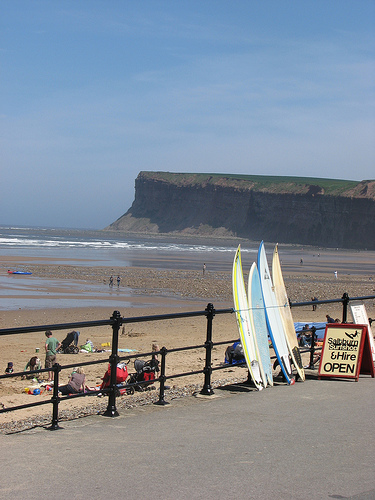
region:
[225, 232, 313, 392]
Surfboards leaning against rail.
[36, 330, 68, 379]
Man standing on beach dressed in green shirt.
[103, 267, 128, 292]
People walking along beach.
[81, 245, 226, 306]
Evidence of low tide.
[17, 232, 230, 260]
White caps of breaking waves on shore.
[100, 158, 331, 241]
A bluff over looking ocean.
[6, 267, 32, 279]
Blue boat stranded on beach.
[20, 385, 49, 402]
Children's toys laying on beach.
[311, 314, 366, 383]
Tan surfing lesson sign trimmed in brown.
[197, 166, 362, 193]
Grass on top of bluff.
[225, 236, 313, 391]
four surfboards leaning on rail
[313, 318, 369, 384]
surf shop open sign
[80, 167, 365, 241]
large bluff above ocean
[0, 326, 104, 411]
beachgoers picnicing in sand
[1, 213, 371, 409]
beach scene at low tide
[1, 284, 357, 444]
black iron fence in front of beach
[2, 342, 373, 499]
asphalt boardwalk at beach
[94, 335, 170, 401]
red strollers at beach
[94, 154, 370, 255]
large grassy bluff above beach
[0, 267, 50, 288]
kayak on beach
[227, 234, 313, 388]
surfboards leaning on railing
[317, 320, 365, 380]
rental shop sign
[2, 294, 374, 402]
railing on concrete boardwalk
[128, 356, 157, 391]
baby stroller on beach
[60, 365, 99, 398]
woman sitting on beach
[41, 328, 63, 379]
man standing on beach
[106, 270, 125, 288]
two people walking in shallow water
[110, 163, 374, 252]
cliff overlooking water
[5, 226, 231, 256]
ocean water coming into beach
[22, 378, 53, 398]
children's sand toys on beach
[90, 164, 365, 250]
Cliff near the seashore.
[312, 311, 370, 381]
Red and yellow sign on the boardwalk.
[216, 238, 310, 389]
Four surfboards leaning on a railing.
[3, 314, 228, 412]
Black railing on the boardwalk.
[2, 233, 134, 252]
Waves coming onto the shore.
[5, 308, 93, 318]
Sandy beach along the coastline.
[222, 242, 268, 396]
Yellow and white surfboard.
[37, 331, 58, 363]
Child in a green shirt on the beach.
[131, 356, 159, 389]
Stroller parked in the sand.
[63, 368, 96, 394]
Woman sitting on the sand.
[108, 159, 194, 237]
large cliff over water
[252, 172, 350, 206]
grass on the cliff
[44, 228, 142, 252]
white waves coming to the shore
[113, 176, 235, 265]
shadow on the rocks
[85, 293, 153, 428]
black posts in the asphalt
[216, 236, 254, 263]
tip of yellow surf board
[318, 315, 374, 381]
large square tan sign with red edges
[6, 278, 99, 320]
water on the sand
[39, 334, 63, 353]
man wearing green shirt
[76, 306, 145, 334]
decorative edge of iron railing